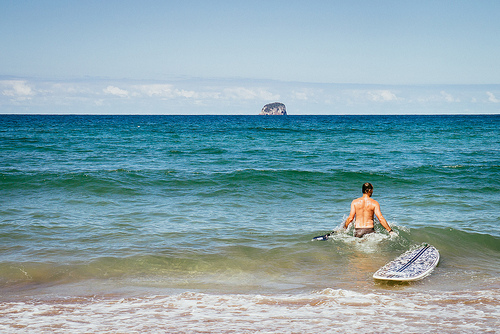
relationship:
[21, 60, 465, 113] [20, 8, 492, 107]
clouds in sky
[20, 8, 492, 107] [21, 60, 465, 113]
sky has clouds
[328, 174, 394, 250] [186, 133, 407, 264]
man in water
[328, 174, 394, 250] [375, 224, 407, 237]
man extending hand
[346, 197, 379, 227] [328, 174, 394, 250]
back of man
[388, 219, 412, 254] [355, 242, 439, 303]
foam in front of board